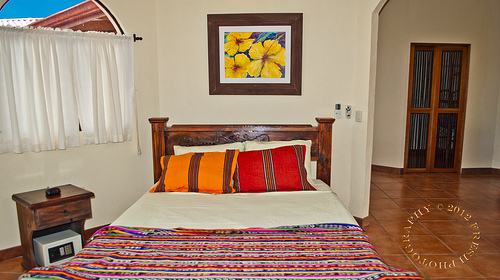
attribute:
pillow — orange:
[157, 151, 238, 194]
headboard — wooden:
[102, 75, 381, 256]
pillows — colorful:
[157, 137, 330, 201]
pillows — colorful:
[176, 118, 313, 152]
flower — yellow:
[208, 33, 321, 103]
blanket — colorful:
[16, 223, 421, 278]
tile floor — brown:
[354, 165, 499, 278]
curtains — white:
[8, 18, 146, 138]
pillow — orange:
[152, 143, 244, 203]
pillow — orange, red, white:
[152, 149, 237, 193]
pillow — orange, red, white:
[233, 143, 319, 192]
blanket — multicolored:
[21, 221, 397, 279]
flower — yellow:
[247, 38, 284, 77]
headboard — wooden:
[172, 120, 214, 149]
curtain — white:
[0, 24, 138, 157]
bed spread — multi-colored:
[18, 204, 425, 276]